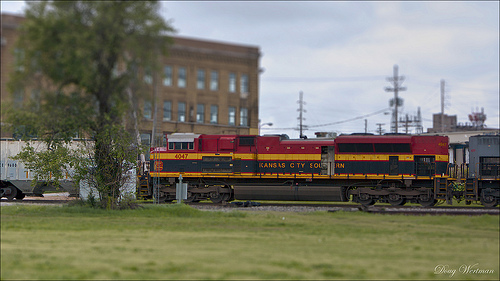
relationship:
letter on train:
[153, 144, 330, 192] [141, 102, 494, 214]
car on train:
[144, 124, 454, 213] [1, 130, 499, 222]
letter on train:
[263, 163, 268, 168] [141, 123, 454, 205]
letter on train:
[258, 159, 263, 173] [141, 113, 463, 203]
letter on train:
[278, 161, 287, 168] [148, 130, 448, 208]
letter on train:
[262, 162, 269, 169] [147, 121, 499, 209]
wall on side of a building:
[58, 34, 299, 200] [38, 17, 496, 248]